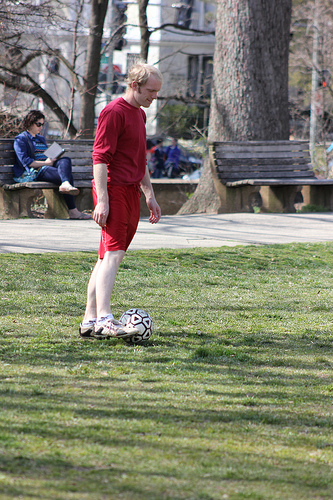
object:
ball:
[118, 305, 153, 341]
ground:
[170, 301, 243, 358]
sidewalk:
[141, 211, 333, 247]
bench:
[211, 137, 333, 189]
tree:
[176, 0, 291, 216]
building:
[1, 1, 219, 127]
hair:
[128, 62, 162, 80]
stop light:
[322, 78, 328, 90]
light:
[320, 79, 328, 89]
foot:
[57, 180, 78, 194]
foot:
[67, 209, 91, 219]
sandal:
[59, 178, 77, 194]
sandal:
[67, 211, 93, 219]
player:
[78, 61, 162, 338]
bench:
[1, 136, 94, 217]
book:
[43, 141, 66, 160]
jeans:
[38, 156, 77, 185]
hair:
[21, 109, 45, 128]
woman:
[13, 109, 89, 218]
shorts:
[90, 175, 142, 263]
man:
[74, 60, 165, 340]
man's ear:
[131, 82, 140, 90]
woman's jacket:
[12, 129, 53, 174]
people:
[148, 124, 191, 178]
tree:
[1, 4, 110, 141]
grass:
[0, 241, 332, 496]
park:
[0, 0, 325, 497]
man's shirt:
[89, 98, 157, 192]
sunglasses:
[28, 120, 46, 127]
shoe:
[93, 316, 132, 339]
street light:
[105, 0, 124, 57]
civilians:
[146, 119, 201, 186]